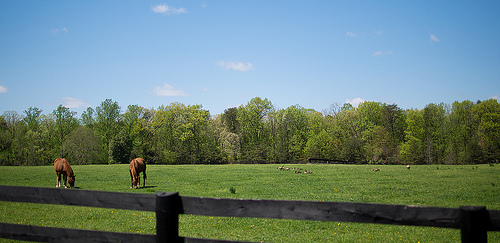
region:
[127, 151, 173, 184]
brown horse in pasture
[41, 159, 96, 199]
brown horse in pasture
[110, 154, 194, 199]
brown horse on grass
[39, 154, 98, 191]
brown horse on ground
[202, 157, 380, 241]
green grass in pasture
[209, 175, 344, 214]
wood fence by grass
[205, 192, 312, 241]
black paint on fence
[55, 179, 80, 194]
white feet on horse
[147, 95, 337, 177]
tall trees behind horse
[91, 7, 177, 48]
blue sky above trees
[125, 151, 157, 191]
horse in a field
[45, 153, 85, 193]
horse in a field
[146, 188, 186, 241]
wooden fence post on a fence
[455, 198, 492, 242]
wooden fence post on a fence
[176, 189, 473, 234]
wooden slat on a fence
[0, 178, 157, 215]
wooden slat on a fence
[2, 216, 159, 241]
wooden slat on a fence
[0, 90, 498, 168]
row of trees behind the field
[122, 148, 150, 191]
horse eating some grass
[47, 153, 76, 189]
horse eating some grass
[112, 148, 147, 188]
brown horse in field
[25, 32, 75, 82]
white clouds in blue sky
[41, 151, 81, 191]
brown horse in field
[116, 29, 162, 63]
white clouds in blue sky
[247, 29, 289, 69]
white clouds in blue sky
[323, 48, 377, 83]
white clouds in blue sky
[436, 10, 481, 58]
white clouds in blue sky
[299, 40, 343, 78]
white clouds in blue sky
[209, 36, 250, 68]
white clouds in blue sky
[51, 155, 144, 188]
two brown horses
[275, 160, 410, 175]
several geese grazing in the field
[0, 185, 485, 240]
black split rail fence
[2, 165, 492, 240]
green grass pasture for grasing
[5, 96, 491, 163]
a forest of green trees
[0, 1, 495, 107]
clear blue sky with a few puffy clouds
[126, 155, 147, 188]
the brown horse on the right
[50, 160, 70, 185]
the horse on the left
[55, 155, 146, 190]
two horses grazing in a field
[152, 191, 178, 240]
the black fence post on the left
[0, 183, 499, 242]
A wooden rail fence.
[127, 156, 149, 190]
A brown colored horse.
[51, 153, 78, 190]
A brown horse grazing.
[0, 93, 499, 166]
A background of green trees.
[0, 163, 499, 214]
A large green pasture.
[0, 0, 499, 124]
A blue sky with small white clouds.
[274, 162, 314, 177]
A small group of animals in a pasture.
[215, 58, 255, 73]
A small white cloud.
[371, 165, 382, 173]
An animal in a pasture.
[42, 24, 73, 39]
A small wispy cloud.